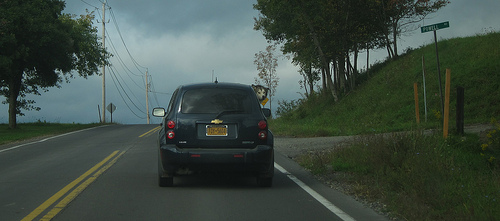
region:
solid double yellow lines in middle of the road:
[11, 139, 132, 219]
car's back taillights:
[161, 114, 273, 161]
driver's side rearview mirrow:
[151, 104, 165, 122]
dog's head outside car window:
[249, 81, 273, 105]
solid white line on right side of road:
[272, 158, 356, 219]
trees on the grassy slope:
[256, 0, 414, 133]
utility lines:
[95, 4, 154, 117]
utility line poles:
[97, 2, 151, 126]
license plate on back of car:
[201, 121, 232, 138]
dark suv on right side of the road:
[153, 76, 280, 192]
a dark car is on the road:
[148, 68, 285, 198]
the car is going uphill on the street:
[131, 71, 290, 219]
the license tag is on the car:
[204, 124, 229, 138]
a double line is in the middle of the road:
[23, 120, 226, 210]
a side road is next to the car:
[241, 107, 486, 193]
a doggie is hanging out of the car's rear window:
[246, 74, 279, 108]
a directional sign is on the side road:
[413, 15, 457, 91]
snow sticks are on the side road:
[401, 60, 463, 155]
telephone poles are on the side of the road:
[81, 1, 171, 133]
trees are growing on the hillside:
[201, 3, 417, 154]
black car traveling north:
[167, 79, 284, 192]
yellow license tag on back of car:
[197, 108, 242, 138]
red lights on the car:
[158, 109, 185, 148]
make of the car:
[205, 114, 228, 127]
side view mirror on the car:
[153, 100, 167, 120]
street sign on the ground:
[408, 17, 453, 119]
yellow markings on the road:
[26, 147, 134, 219]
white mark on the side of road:
[273, 174, 356, 219]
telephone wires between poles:
[96, 2, 148, 128]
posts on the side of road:
[438, 74, 472, 139]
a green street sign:
[416, 20, 451, 31]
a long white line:
[269, 156, 348, 219]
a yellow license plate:
[207, 122, 234, 137]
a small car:
[157, 78, 279, 190]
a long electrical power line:
[104, 9, 152, 75]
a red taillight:
[257, 118, 267, 133]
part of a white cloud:
[132, 23, 249, 78]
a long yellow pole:
[407, 80, 427, 127]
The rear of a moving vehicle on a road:
[150, 68, 282, 201]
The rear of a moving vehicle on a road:
[147, 73, 279, 203]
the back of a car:
[133, 73, 280, 187]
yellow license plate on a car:
[201, 123, 232, 139]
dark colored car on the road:
[150, 79, 283, 188]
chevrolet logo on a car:
[208, 117, 224, 126]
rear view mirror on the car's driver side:
[147, 104, 169, 119]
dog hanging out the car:
[251, 78, 273, 101]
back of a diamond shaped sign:
[103, 98, 119, 112]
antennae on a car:
[215, 76, 219, 83]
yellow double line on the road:
[26, 118, 164, 218]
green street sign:
[418, 18, 453, 34]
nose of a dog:
[259, 93, 266, 99]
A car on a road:
[160, 80, 273, 182]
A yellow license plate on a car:
[204, 120, 228, 137]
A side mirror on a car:
[150, 105, 168, 115]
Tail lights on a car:
[254, 116, 268, 138]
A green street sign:
[420, 20, 447, 30]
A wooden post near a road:
[442, 68, 450, 138]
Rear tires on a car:
[157, 162, 274, 188]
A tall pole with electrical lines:
[97, 3, 109, 120]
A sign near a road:
[105, 102, 116, 124]